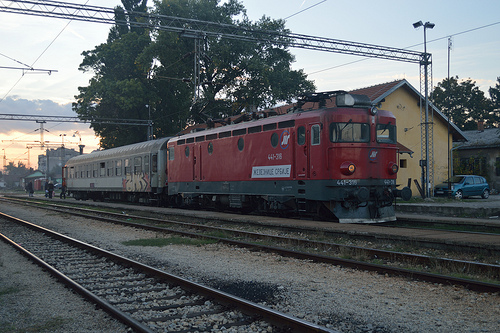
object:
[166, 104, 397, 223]
train engine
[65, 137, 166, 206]
passenger car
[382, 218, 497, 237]
tracks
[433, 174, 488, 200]
car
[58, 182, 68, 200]
person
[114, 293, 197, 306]
gravel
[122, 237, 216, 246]
grass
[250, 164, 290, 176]
writting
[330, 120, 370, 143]
window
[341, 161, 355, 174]
light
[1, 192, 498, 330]
ground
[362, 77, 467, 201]
building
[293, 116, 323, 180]
door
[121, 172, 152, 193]
graffiti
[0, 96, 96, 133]
cloud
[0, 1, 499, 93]
sky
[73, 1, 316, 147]
tree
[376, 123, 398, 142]
window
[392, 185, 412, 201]
safety ram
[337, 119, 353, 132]
windsheild wiper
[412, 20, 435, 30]
lights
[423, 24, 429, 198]
pole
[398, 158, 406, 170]
window